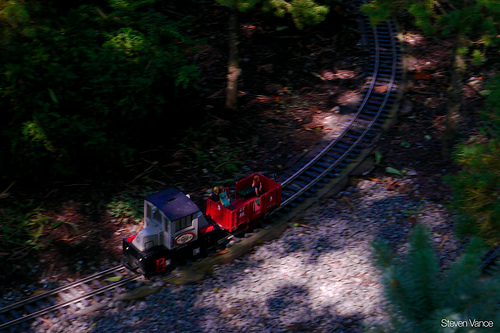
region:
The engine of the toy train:
[118, 187, 205, 275]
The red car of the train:
[200, 165, 287, 245]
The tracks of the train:
[0, 5, 402, 332]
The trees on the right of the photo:
[379, 2, 498, 332]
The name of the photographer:
[438, 311, 496, 329]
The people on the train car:
[208, 171, 263, 206]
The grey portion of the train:
[118, 183, 207, 276]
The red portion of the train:
[197, 162, 285, 242]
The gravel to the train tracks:
[2, 178, 464, 330]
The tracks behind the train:
[290, 0, 401, 193]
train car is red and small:
[204, 167, 294, 239]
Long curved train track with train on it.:
[0, 2, 452, 332]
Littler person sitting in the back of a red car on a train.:
[248, 172, 263, 197]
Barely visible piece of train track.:
[425, 219, 497, 331]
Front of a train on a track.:
[122, 187, 228, 279]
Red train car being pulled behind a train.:
[205, 170, 285, 232]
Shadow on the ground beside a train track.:
[366, 187, 423, 241]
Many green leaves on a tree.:
[105, 28, 142, 55]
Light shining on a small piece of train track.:
[57, 287, 97, 306]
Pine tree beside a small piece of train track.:
[370, 222, 497, 331]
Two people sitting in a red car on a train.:
[207, 185, 231, 212]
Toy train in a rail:
[104, 146, 296, 266]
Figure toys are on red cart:
[208, 169, 270, 211]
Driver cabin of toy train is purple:
[102, 178, 222, 283]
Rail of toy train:
[268, 12, 424, 182]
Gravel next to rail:
[235, 210, 450, 327]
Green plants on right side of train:
[382, 127, 499, 322]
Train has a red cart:
[194, 158, 293, 238]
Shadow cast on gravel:
[255, 262, 324, 319]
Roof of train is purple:
[139, 179, 203, 224]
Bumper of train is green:
[112, 238, 153, 283]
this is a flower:
[408, 236, 490, 330]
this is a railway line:
[299, 110, 387, 172]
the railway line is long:
[306, 108, 379, 193]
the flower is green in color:
[415, 234, 473, 329]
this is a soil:
[258, 60, 330, 105]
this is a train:
[126, 179, 282, 240]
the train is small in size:
[118, 190, 288, 272]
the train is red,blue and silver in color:
[121, 172, 273, 276]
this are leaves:
[21, 14, 113, 101]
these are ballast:
[228, 277, 356, 317]